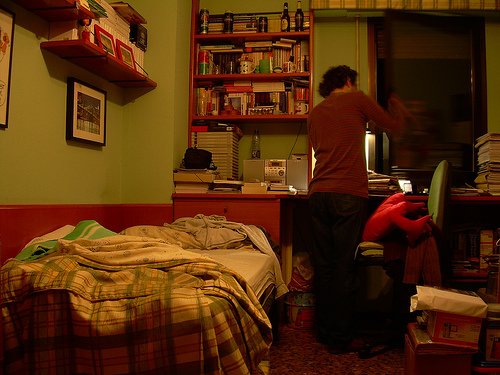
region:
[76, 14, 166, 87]
red frames on shelf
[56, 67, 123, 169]
black framed picture on wall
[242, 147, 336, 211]
silver stereo on table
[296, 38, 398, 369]
man standing near table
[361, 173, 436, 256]
red pillow on chair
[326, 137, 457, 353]
green swivel chair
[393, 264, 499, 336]
copier paper on box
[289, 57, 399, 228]
red striped shirt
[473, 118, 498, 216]
stack of book on table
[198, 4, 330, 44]
bottles and cans on shelf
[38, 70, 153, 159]
black picture framed picture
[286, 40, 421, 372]
boy standing in bedroom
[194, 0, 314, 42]
empty beer bottles on shelf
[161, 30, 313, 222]
books on shelf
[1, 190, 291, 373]
unmade bed in bedroom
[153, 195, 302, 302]
grey sweat pants on bed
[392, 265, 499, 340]
copier paper on boxes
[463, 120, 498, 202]
stack of books on table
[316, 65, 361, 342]
person wearing jeans and a striped shirt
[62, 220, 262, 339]
unmade bed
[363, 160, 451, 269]
green office chair with a pillow on it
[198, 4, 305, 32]
beer bottles and cans on a shelf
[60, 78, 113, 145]
framed artwork on the wall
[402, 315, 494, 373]
cardboard boxes stacked on the floor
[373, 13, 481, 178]
window above the desk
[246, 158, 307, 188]
silver stereo and speakers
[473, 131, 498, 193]
stack of books on the desk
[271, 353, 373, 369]
carpeted bedroom floor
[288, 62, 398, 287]
the boy is wearing red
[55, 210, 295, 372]
the bed is unmade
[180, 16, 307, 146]
books on shelf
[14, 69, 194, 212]
wall is green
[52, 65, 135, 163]
there is a picture on the wall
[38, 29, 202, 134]
there is a shelf made of wood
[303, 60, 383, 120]
the boy has brown hair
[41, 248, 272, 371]
the blanket is plaid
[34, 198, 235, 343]
there is blanket on the bed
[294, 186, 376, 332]
the boys pants are black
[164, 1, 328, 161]
RED CLUTTERED SHELF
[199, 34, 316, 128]
SEVERAL BOOKS ON SHELF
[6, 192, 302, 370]
THE BED IS UNMADE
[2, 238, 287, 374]
BEDSPREAD AT FOOT OF BED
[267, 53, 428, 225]
MAN IN RED COLORED SHIRT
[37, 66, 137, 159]
PICTURE HANGING ON WALL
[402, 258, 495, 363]
PAPER WRAPPED PACKAGE ON TOP OF BOX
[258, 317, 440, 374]
RED COLORED CARPET ON FLOOR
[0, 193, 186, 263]
RED PANELING AT BOTTOM OF WALL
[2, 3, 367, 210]
WALL IS PAINTED GREEN